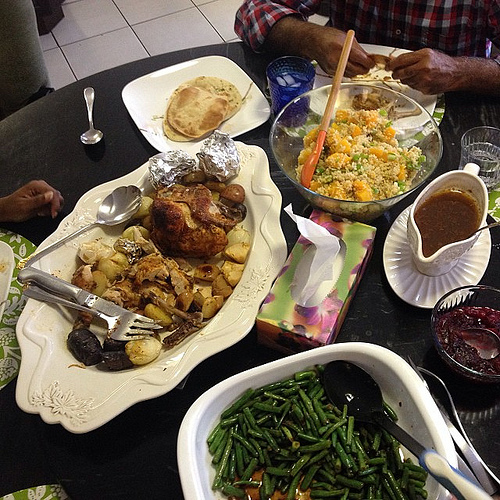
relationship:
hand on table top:
[4, 175, 64, 226] [5, 120, 70, 171]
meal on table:
[85, 121, 421, 468] [4, 37, 498, 447]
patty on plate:
[165, 73, 244, 163] [97, 40, 268, 102]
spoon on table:
[78, 81, 103, 147] [2, 35, 499, 497]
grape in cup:
[435, 307, 498, 363] [428, 283, 498, 381]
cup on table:
[428, 283, 498, 381] [2, 35, 499, 497]